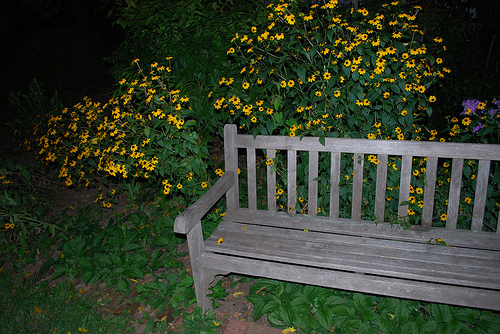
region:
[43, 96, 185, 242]
Yellow flowers are growing from the ground.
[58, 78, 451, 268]
Yellow flowers are next to a bench.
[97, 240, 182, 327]
Weeds are growing from the ground.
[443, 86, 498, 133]
Purple flowers are growing with yellow flowers.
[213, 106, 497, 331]
A bench stands in front of flowers.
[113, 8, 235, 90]
A green bush is behind yellow flowers.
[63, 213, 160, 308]
Weeds are growing next to yellow flowers.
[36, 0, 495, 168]
A bouquet of flowers blossm behind a bench.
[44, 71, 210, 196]
Yellow flowers are growing with green leaves.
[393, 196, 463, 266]
A flower is blooming through a bench.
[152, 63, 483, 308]
a bench in a yard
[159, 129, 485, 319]
the bench is wooden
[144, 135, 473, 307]
the bench is gray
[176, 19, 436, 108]
a flower bush behind the bench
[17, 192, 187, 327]
grass on the ground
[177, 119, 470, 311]
this bench is for seating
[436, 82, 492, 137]
purple flowers in the shot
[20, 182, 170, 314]
dirt patches on the ground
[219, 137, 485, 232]
the back of the bench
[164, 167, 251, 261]
the arms on the bench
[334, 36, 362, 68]
yellow black-eyed susans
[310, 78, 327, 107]
yellow flowers on a bush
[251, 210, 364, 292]
wooden seat of a bench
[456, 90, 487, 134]
purple flowers on a bush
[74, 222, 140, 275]
green leaves on the ground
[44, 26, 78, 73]
darkeness in the background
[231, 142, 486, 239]
wooden back of a bench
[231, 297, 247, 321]
dirt on the ground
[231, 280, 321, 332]
leaves underneath a bench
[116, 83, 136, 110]
yellow flowers on a bush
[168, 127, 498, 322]
a wooden park bench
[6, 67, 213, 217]
a bush featuring black and yellow daisies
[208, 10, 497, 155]
a bush featuring black and yellow daisies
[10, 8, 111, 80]
the midnight black sky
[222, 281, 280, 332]
dirt patch on the ground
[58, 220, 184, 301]
collection of small green shrubs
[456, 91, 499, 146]
a small purple plant behind the daisies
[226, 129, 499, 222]
back rest of the bench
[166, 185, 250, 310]
arm rest of the bench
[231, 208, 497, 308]
wooden seat of the outdoor bench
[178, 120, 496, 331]
this is a bench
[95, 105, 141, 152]
these are yellow flowers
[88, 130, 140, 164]
these are yellow flowers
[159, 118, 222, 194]
these are yellow flowers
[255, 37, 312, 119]
these are yellow flowers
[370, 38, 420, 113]
these are yellow flowers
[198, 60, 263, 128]
these are yellow flowers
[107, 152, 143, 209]
these are yellow flowers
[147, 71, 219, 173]
these are yellow flowers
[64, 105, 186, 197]
these are yellow flowers